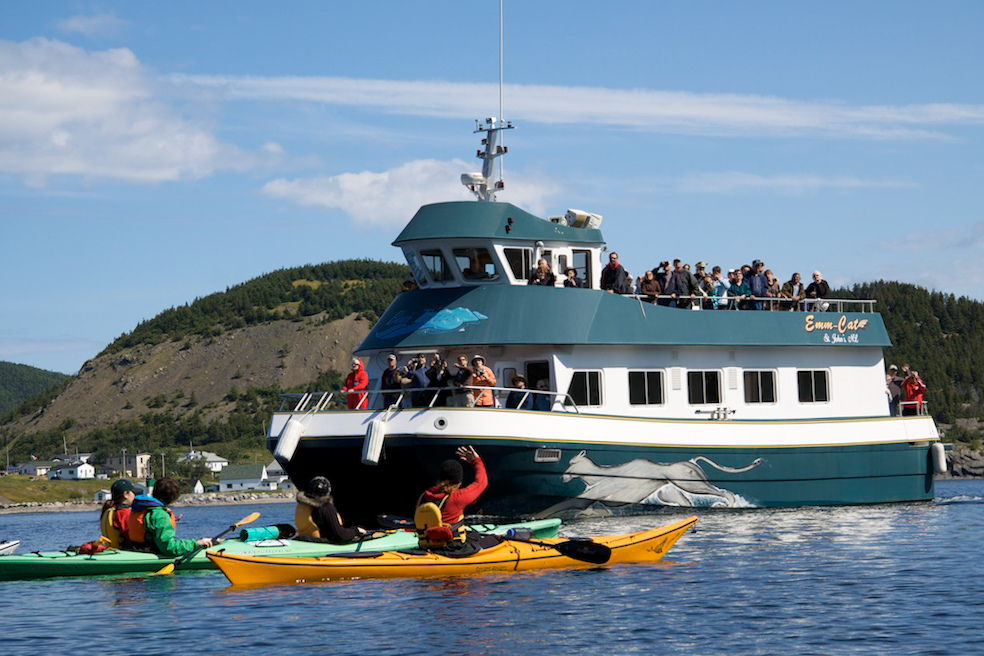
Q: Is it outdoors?
A: Yes, it is outdoors.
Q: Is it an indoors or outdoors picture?
A: It is outdoors.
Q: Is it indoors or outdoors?
A: It is outdoors.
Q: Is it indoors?
A: No, it is outdoors.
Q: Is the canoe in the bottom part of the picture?
A: Yes, the canoe is in the bottom of the image.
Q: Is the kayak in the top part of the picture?
A: No, the kayak is in the bottom of the image.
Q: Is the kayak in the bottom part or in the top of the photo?
A: The kayak is in the bottom of the image.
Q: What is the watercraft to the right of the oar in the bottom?
A: The watercraft is a canoe.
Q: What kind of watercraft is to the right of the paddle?
A: The watercraft is a canoe.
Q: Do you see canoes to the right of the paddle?
A: Yes, there is a canoe to the right of the paddle.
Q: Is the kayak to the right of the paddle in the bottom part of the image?
A: Yes, the kayak is to the right of the oar.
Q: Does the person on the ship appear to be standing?
A: Yes, the person is standing.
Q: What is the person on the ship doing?
A: The person is standing.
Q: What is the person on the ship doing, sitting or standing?
A: The person is standing.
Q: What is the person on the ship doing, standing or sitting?
A: The person is standing.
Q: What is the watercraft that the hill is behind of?
A: The watercraft is a ship.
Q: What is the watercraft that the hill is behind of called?
A: The watercraft is a ship.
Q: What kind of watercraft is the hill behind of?
A: The hill is behind the ship.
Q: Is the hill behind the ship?
A: Yes, the hill is behind the ship.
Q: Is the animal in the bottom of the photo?
A: Yes, the animal is in the bottom of the image.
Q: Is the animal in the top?
A: No, the animal is in the bottom of the image.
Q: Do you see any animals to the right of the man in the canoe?
A: Yes, there is an animal to the right of the man.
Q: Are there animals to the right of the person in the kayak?
A: Yes, there is an animal to the right of the man.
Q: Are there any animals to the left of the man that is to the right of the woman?
A: No, the animal is to the right of the man.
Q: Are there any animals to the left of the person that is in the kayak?
A: No, the animal is to the right of the man.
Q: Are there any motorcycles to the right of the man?
A: No, there is an animal to the right of the man.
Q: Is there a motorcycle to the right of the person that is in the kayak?
A: No, there is an animal to the right of the man.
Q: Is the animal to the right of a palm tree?
A: No, the animal is to the right of the man.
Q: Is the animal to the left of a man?
A: No, the animal is to the right of a man.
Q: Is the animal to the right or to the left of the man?
A: The animal is to the right of the man.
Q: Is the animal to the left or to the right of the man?
A: The animal is to the right of the man.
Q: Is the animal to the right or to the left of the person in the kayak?
A: The animal is to the right of the man.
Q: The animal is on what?
A: The animal is on the ship.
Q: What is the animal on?
A: The animal is on the ship.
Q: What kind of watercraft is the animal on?
A: The animal is on the ship.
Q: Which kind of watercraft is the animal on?
A: The animal is on the ship.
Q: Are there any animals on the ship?
A: Yes, there is an animal on the ship.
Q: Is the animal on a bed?
A: No, the animal is on the ship.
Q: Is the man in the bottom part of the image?
A: Yes, the man is in the bottom of the image.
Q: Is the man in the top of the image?
A: No, the man is in the bottom of the image.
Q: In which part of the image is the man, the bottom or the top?
A: The man is in the bottom of the image.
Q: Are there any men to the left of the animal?
A: Yes, there is a man to the left of the animal.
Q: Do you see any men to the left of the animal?
A: Yes, there is a man to the left of the animal.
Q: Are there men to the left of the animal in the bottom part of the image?
A: Yes, there is a man to the left of the animal.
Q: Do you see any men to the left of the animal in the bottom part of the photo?
A: Yes, there is a man to the left of the animal.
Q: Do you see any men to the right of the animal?
A: No, the man is to the left of the animal.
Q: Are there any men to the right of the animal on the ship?
A: No, the man is to the left of the animal.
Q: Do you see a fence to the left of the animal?
A: No, there is a man to the left of the animal.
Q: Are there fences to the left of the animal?
A: No, there is a man to the left of the animal.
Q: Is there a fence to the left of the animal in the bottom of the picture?
A: No, there is a man to the left of the animal.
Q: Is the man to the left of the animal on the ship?
A: Yes, the man is to the left of the animal.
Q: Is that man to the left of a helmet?
A: No, the man is to the left of the animal.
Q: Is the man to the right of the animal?
A: No, the man is to the left of the animal.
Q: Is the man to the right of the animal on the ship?
A: No, the man is to the left of the animal.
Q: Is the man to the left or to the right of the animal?
A: The man is to the left of the animal.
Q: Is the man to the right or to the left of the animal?
A: The man is to the left of the animal.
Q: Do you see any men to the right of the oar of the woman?
A: Yes, there is a man to the right of the oar.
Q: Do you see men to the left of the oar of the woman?
A: No, the man is to the right of the oar.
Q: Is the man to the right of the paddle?
A: Yes, the man is to the right of the paddle.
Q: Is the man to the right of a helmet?
A: No, the man is to the right of the paddle.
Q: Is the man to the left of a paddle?
A: No, the man is to the right of a paddle.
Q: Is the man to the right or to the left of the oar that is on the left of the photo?
A: The man is to the right of the oar.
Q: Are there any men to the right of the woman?
A: Yes, there is a man to the right of the woman.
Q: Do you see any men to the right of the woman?
A: Yes, there is a man to the right of the woman.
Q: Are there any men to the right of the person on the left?
A: Yes, there is a man to the right of the woman.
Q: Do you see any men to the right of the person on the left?
A: Yes, there is a man to the right of the woman.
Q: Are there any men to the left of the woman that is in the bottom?
A: No, the man is to the right of the woman.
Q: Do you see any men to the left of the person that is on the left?
A: No, the man is to the right of the woman.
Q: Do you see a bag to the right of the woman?
A: No, there is a man to the right of the woman.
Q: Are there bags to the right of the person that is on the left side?
A: No, there is a man to the right of the woman.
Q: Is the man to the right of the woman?
A: Yes, the man is to the right of the woman.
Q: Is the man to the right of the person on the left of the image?
A: Yes, the man is to the right of the woman.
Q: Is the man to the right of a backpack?
A: No, the man is to the right of the woman.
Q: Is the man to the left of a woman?
A: No, the man is to the right of a woman.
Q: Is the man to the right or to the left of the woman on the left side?
A: The man is to the right of the woman.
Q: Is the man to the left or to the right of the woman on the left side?
A: The man is to the right of the woman.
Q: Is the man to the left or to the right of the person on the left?
A: The man is to the right of the woman.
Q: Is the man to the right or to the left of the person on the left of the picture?
A: The man is to the right of the woman.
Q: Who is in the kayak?
A: The man is in the kayak.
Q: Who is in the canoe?
A: The man is in the kayak.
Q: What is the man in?
A: The man is in the canoe.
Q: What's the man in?
A: The man is in the canoe.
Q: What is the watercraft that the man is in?
A: The watercraft is a canoe.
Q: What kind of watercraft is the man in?
A: The man is in the kayak.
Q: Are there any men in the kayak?
A: Yes, there is a man in the kayak.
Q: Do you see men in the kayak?
A: Yes, there is a man in the kayak.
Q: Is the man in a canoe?
A: Yes, the man is in a canoe.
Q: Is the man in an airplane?
A: No, the man is in a canoe.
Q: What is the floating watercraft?
A: The watercraft is a ship.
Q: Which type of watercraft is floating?
A: The watercraft is a ship.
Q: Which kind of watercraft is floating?
A: The watercraft is a ship.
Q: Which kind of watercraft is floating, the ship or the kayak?
A: The ship is floating.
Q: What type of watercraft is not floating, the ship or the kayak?
A: The kayak is not floating.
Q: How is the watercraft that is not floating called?
A: The watercraft is a canoe.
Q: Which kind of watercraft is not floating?
A: The watercraft is a canoe.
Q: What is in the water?
A: The ship is in the water.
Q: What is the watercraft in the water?
A: The watercraft is a ship.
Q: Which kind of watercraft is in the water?
A: The watercraft is a ship.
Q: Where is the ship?
A: The ship is in the water.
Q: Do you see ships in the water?
A: Yes, there is a ship in the water.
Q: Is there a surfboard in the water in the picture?
A: No, there is a ship in the water.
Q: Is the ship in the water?
A: Yes, the ship is in the water.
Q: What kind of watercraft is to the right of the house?
A: The watercraft is a ship.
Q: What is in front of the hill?
A: The ship is in front of the hill.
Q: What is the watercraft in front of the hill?
A: The watercraft is a ship.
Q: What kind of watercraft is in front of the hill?
A: The watercraft is a ship.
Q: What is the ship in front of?
A: The ship is in front of the hill.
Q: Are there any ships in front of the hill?
A: Yes, there is a ship in front of the hill.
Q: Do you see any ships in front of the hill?
A: Yes, there is a ship in front of the hill.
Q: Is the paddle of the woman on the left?
A: Yes, the oar is on the left of the image.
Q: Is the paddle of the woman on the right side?
A: No, the oar is on the left of the image.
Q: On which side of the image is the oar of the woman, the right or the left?
A: The paddle is on the left of the image.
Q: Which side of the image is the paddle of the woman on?
A: The paddle is on the left of the image.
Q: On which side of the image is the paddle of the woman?
A: The paddle is on the left of the image.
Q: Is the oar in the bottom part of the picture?
A: Yes, the oar is in the bottom of the image.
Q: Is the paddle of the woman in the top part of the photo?
A: No, the oar is in the bottom of the image.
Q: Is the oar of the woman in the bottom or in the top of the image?
A: The oar is in the bottom of the image.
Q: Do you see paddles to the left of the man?
A: Yes, there is a paddle to the left of the man.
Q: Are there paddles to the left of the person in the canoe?
A: Yes, there is a paddle to the left of the man.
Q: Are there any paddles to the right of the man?
A: No, the paddle is to the left of the man.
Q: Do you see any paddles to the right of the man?
A: No, the paddle is to the left of the man.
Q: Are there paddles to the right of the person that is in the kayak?
A: No, the paddle is to the left of the man.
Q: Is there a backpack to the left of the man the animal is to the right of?
A: No, there is a paddle to the left of the man.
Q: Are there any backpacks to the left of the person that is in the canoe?
A: No, there is a paddle to the left of the man.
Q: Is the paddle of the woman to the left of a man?
A: Yes, the paddle is to the left of a man.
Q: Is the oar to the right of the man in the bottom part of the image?
A: No, the oar is to the left of the man.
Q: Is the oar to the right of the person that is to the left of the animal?
A: No, the oar is to the left of the man.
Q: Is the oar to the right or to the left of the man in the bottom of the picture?
A: The oar is to the left of the man.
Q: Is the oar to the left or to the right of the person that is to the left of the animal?
A: The oar is to the left of the man.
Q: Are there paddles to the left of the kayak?
A: Yes, there is a paddle to the left of the kayak.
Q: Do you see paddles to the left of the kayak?
A: Yes, there is a paddle to the left of the kayak.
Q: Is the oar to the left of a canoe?
A: Yes, the oar is to the left of a canoe.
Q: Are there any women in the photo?
A: Yes, there is a woman.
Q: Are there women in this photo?
A: Yes, there is a woman.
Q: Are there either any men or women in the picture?
A: Yes, there is a woman.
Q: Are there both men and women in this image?
A: Yes, there are both a woman and a man.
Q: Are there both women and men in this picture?
A: Yes, there are both a woman and a man.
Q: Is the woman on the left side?
A: Yes, the woman is on the left of the image.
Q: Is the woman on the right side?
A: No, the woman is on the left of the image.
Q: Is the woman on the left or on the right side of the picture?
A: The woman is on the left of the image.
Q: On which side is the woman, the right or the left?
A: The woman is on the left of the image.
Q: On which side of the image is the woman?
A: The woman is on the left of the image.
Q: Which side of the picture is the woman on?
A: The woman is on the left of the image.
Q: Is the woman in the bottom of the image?
A: Yes, the woman is in the bottom of the image.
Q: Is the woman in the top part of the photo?
A: No, the woman is in the bottom of the image.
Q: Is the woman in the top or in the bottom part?
A: The woman is in the bottom of the image.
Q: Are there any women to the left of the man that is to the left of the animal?
A: Yes, there is a woman to the left of the man.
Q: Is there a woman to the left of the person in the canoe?
A: Yes, there is a woman to the left of the man.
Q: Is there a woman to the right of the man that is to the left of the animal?
A: No, the woman is to the left of the man.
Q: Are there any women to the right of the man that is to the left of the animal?
A: No, the woman is to the left of the man.